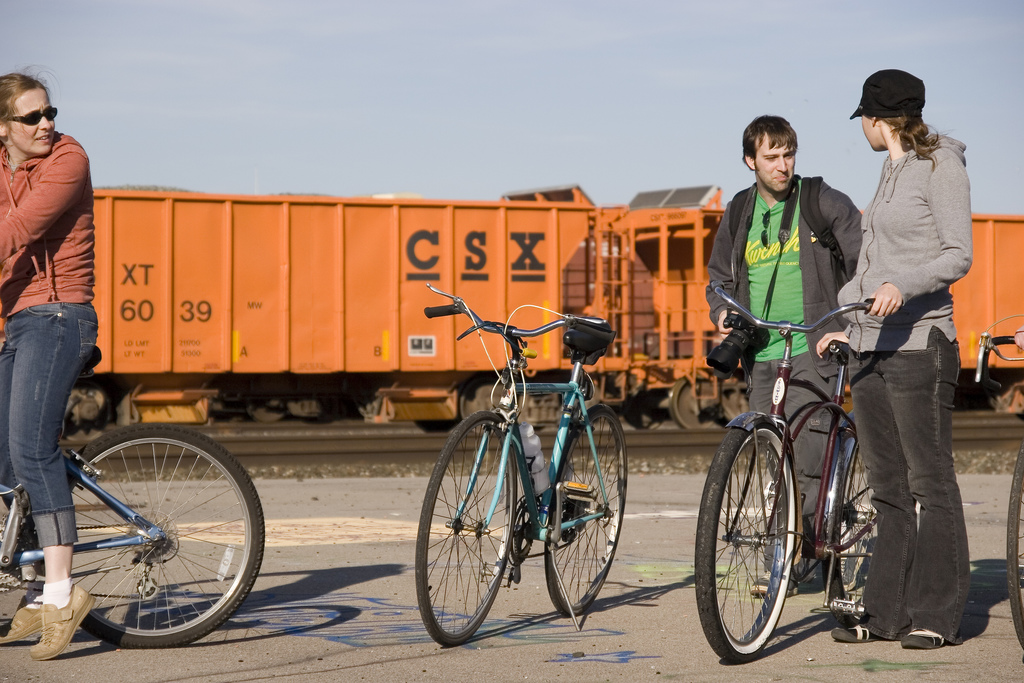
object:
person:
[706, 117, 867, 597]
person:
[829, 65, 969, 650]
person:
[0, 69, 101, 660]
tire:
[66, 422, 266, 651]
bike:
[0, 349, 268, 651]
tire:
[414, 410, 518, 647]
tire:
[544, 403, 629, 616]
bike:
[414, 283, 628, 646]